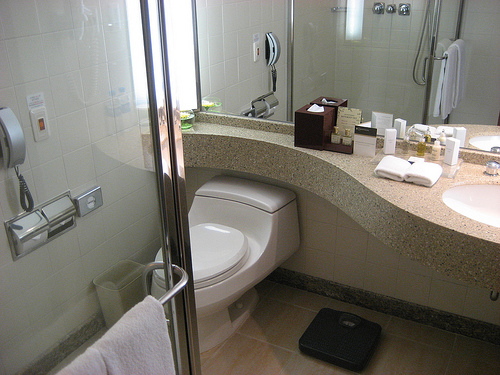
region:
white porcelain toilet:
[152, 173, 304, 351]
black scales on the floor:
[296, 303, 385, 368]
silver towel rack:
[160, 262, 191, 307]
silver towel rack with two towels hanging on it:
[58, 262, 190, 373]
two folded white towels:
[372, 150, 443, 187]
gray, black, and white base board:
[265, 264, 497, 344]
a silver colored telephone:
[0, 105, 35, 212]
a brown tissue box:
[293, 103, 336, 148]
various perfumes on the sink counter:
[376, 125, 460, 166]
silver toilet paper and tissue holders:
[3, 185, 108, 262]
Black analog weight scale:
[295, 305, 384, 370]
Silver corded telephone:
[0, 105, 34, 211]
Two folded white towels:
[372, 153, 442, 186]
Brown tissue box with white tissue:
[293, 101, 335, 150]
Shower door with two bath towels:
[420, 0, 466, 122]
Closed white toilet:
[150, 173, 302, 351]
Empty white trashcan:
[90, 258, 151, 330]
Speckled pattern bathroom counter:
[140, 110, 498, 291]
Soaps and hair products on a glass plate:
[370, 125, 464, 179]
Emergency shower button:
[28, 105, 50, 143]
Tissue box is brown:
[289, 99, 338, 150]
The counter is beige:
[161, 102, 492, 287]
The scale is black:
[294, 296, 384, 369]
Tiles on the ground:
[156, 289, 493, 372]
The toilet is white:
[146, 170, 296, 360]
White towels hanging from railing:
[57, 271, 187, 373]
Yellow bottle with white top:
[413, 134, 428, 158]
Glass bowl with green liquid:
[179, 102, 199, 133]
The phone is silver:
[1, 105, 36, 211]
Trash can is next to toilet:
[93, 259, 147, 326]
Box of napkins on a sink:
[296, 91, 333, 140]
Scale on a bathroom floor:
[301, 301, 377, 365]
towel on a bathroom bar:
[51, 283, 133, 372]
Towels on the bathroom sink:
[373, 156, 425, 198]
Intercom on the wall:
[5, 108, 45, 215]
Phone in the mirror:
[261, 32, 298, 83]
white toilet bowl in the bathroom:
[198, 190, 293, 293]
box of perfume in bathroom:
[444, 134, 464, 169]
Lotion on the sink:
[381, 123, 406, 160]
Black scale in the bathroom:
[316, 281, 380, 368]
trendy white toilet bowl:
[146, 170, 309, 355]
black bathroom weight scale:
[296, 303, 383, 373]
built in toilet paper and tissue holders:
[6, 189, 122, 266]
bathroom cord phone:
[1, 105, 48, 217]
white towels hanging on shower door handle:
[34, 261, 214, 373]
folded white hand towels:
[368, 152, 442, 196]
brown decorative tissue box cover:
[290, 98, 340, 154]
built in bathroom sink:
[442, 152, 497, 227]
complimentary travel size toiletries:
[333, 105, 464, 172]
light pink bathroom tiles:
[216, 288, 496, 374]